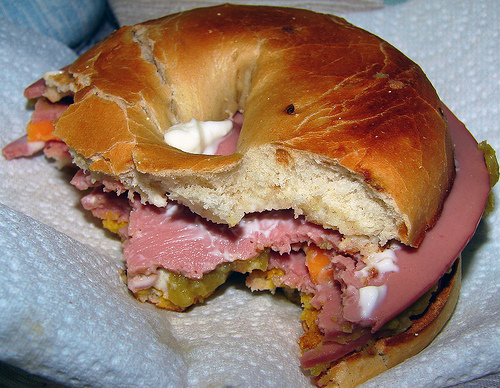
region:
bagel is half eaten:
[0, 1, 495, 377]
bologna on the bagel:
[70, 78, 499, 317]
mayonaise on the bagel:
[131, 82, 444, 326]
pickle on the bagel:
[140, 240, 240, 297]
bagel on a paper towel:
[0, 0, 497, 359]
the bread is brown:
[38, 6, 499, 291]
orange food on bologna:
[282, 223, 357, 295]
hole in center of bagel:
[124, 72, 256, 174]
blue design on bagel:
[0, 1, 101, 45]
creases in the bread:
[295, 43, 407, 158]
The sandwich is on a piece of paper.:
[1, 0, 498, 386]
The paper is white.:
[1, 0, 498, 387]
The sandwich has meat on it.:
[2, 58, 490, 368]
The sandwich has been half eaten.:
[2, 0, 499, 387]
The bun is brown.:
[48, 0, 453, 253]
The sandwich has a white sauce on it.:
[160, 113, 234, 163]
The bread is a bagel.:
[46, 5, 459, 387]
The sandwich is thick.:
[27, 3, 462, 386]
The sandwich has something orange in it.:
[304, 245, 338, 285]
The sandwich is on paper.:
[1, 1, 498, 386]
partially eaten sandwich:
[1, 11, 480, 385]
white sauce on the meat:
[354, 281, 384, 322]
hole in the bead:
[152, 93, 253, 165]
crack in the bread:
[132, 24, 173, 84]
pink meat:
[117, 206, 272, 281]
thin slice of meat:
[365, 104, 492, 334]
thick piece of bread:
[52, 9, 479, 256]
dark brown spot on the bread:
[337, 68, 432, 167]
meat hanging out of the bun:
[415, 104, 499, 296]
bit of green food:
[472, 136, 499, 183]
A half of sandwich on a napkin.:
[63, 23, 468, 237]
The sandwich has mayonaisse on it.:
[171, 108, 224, 153]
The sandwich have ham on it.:
[128, 200, 298, 260]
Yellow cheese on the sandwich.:
[301, 247, 339, 291]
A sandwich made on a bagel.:
[56, 43, 464, 214]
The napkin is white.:
[48, 275, 382, 385]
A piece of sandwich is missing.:
[91, 140, 433, 319]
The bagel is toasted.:
[266, 43, 406, 198]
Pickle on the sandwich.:
[137, 263, 247, 311]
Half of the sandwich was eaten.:
[70, 87, 440, 337]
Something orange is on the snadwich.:
[303, 245, 335, 286]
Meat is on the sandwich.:
[3, 72, 490, 367]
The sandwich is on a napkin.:
[0, 0, 498, 385]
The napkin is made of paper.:
[0, 0, 497, 387]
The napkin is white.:
[0, 0, 498, 385]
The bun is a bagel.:
[45, 5, 461, 387]